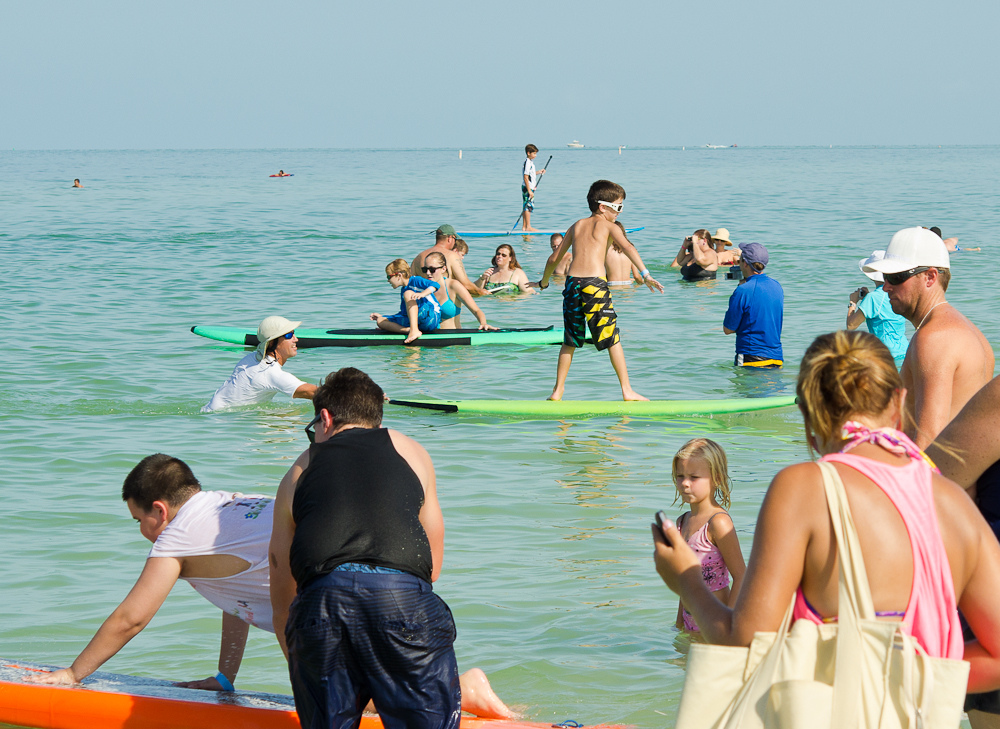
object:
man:
[862, 227, 994, 498]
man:
[722, 242, 784, 373]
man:
[409, 224, 494, 331]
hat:
[863, 225, 951, 274]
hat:
[738, 242, 770, 273]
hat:
[254, 315, 303, 362]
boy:
[525, 179, 667, 401]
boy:
[263, 365, 461, 729]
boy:
[22, 447, 527, 718]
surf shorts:
[562, 275, 622, 351]